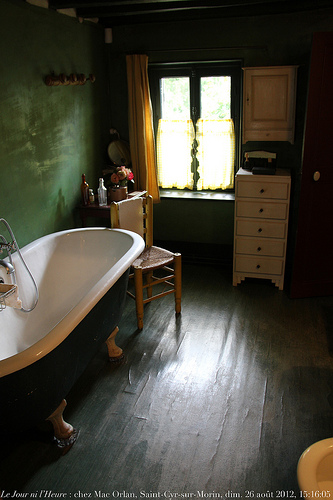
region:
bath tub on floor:
[1, 209, 133, 476]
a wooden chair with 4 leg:
[107, 194, 188, 325]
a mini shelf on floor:
[222, 157, 294, 301]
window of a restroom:
[127, 59, 244, 197]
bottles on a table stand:
[75, 168, 134, 205]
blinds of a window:
[116, 49, 164, 203]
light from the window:
[158, 315, 255, 393]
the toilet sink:
[288, 428, 330, 498]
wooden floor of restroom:
[174, 331, 288, 431]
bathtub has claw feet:
[0, 222, 147, 440]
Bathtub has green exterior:
[3, 222, 141, 444]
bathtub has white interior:
[3, 225, 148, 446]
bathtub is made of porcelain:
[7, 223, 148, 440]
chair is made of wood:
[112, 196, 185, 322]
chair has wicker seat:
[114, 194, 182, 322]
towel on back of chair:
[107, 194, 181, 328]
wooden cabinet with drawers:
[231, 168, 289, 291]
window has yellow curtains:
[154, 118, 235, 190]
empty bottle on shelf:
[96, 179, 106, 205]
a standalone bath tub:
[4, 209, 161, 460]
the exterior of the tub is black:
[1, 213, 164, 461]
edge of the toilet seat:
[295, 430, 332, 497]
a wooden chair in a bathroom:
[102, 187, 189, 334]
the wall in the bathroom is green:
[7, 9, 139, 299]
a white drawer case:
[220, 160, 304, 291]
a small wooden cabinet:
[228, 57, 307, 149]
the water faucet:
[1, 255, 24, 286]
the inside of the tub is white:
[5, 218, 153, 374]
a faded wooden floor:
[62, 288, 295, 493]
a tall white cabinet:
[233, 170, 287, 290]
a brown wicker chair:
[110, 197, 186, 325]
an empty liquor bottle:
[97, 179, 108, 207]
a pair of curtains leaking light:
[156, 116, 234, 187]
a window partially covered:
[149, 62, 233, 196]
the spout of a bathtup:
[0, 253, 18, 281]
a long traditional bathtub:
[0, 219, 148, 437]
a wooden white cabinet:
[244, 64, 292, 141]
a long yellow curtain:
[131, 51, 159, 201]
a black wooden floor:
[114, 316, 323, 499]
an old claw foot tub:
[0, 219, 146, 452]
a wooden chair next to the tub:
[110, 190, 188, 331]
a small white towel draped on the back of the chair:
[117, 196, 144, 240]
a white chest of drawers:
[230, 162, 291, 290]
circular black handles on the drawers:
[254, 187, 265, 273]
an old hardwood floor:
[0, 270, 331, 498]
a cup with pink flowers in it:
[108, 165, 134, 201]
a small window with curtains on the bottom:
[150, 66, 235, 194]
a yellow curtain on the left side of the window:
[126, 51, 161, 204]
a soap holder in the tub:
[0, 280, 20, 310]